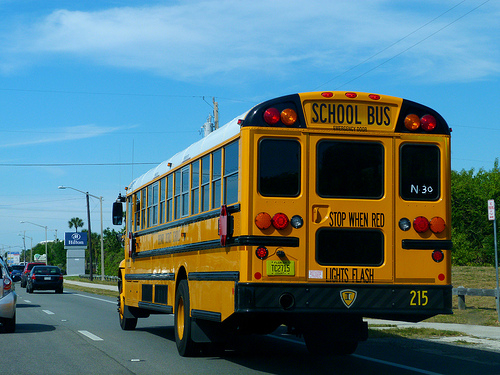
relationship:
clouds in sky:
[53, 19, 193, 71] [2, 31, 239, 148]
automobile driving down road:
[111, 91, 452, 355] [6, 281, 188, 373]